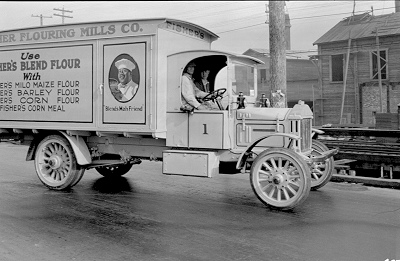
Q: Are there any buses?
A: No, there are no buses.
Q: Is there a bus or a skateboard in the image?
A: No, there are no buses or skateboards.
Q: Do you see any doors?
A: Yes, there is a door.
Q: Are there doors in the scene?
A: Yes, there is a door.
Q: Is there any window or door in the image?
A: Yes, there is a door.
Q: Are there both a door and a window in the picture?
A: Yes, there are both a door and a window.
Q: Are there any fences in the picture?
A: No, there are no fences.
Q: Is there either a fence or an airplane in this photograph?
A: No, there are no fences or airplanes.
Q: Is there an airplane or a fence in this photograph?
A: No, there are no fences or airplanes.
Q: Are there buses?
A: No, there are no buses.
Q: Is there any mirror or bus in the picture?
A: No, there are no buses or mirrors.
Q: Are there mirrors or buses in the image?
A: No, there are no buses or mirrors.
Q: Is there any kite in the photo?
A: No, there are no kites.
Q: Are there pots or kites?
A: No, there are no kites or pots.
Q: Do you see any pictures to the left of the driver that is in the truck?
A: Yes, there is a picture to the left of the driver.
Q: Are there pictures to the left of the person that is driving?
A: Yes, there is a picture to the left of the driver.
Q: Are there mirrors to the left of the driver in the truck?
A: No, there is a picture to the left of the driver.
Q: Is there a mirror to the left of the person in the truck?
A: No, there is a picture to the left of the driver.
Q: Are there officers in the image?
A: No, there are no officers.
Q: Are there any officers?
A: No, there are no officers.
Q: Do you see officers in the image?
A: No, there are no officers.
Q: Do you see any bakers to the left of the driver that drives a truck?
A: Yes, there is a baker to the left of the driver.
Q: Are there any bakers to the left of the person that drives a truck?
A: Yes, there is a baker to the left of the driver.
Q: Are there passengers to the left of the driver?
A: No, there is a baker to the left of the driver.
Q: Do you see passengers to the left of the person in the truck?
A: No, there is a baker to the left of the driver.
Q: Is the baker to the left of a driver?
A: Yes, the baker is to the left of a driver.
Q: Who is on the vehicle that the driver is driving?
A: The baker is on the truck.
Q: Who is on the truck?
A: The baker is on the truck.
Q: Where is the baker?
A: The baker is on the truck.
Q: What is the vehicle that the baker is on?
A: The vehicle is a truck.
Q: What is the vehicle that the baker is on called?
A: The vehicle is a truck.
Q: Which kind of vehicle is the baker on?
A: The baker is on the truck.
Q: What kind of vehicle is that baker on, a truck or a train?
A: The baker is on a truck.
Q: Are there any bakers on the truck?
A: Yes, there is a baker on the truck.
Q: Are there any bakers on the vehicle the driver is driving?
A: Yes, there is a baker on the truck.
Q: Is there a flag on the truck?
A: No, there is a baker on the truck.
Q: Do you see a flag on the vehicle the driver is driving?
A: No, there is a baker on the truck.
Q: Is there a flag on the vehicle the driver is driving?
A: No, there is a baker on the truck.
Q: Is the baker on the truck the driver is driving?
A: Yes, the baker is on the truck.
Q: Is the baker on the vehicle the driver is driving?
A: Yes, the baker is on the truck.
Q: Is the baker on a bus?
A: No, the baker is on the truck.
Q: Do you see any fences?
A: No, there are no fences.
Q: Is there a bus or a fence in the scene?
A: No, there are no fences or buses.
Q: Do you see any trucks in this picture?
A: Yes, there is a truck.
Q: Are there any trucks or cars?
A: Yes, there is a truck.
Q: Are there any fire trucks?
A: No, there are no fire trucks.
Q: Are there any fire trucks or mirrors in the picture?
A: No, there are no fire trucks or mirrors.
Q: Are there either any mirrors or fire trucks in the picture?
A: No, there are no fire trucks or mirrors.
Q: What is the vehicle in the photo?
A: The vehicle is a truck.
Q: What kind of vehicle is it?
A: The vehicle is a truck.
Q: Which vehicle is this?
A: This is a truck.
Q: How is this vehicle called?
A: This is a truck.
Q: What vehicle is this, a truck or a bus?
A: This is a truck.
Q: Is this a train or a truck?
A: This is a truck.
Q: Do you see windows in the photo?
A: Yes, there is a window.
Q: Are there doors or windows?
A: Yes, there is a window.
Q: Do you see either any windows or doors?
A: Yes, there is a window.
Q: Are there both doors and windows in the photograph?
A: Yes, there are both a window and doors.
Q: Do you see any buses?
A: No, there are no buses.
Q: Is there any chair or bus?
A: No, there are no buses or chairs.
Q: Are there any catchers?
A: No, there are no catchers.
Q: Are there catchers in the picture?
A: No, there are no catchers.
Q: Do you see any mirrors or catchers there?
A: No, there are no catchers or mirrors.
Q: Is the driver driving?
A: Yes, the driver is driving.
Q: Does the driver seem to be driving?
A: Yes, the driver is driving.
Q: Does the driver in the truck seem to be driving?
A: Yes, the driver is driving.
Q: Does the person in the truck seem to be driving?
A: Yes, the driver is driving.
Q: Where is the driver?
A: The driver is in the truck.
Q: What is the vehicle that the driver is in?
A: The vehicle is a truck.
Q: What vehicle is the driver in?
A: The driver is in the truck.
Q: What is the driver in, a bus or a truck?
A: The driver is in a truck.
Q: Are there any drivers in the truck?
A: Yes, there is a driver in the truck.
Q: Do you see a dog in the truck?
A: No, there is a driver in the truck.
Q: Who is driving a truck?
A: The driver is driving a truck.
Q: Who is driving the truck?
A: The driver is driving a truck.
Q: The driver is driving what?
A: The driver is driving a truck.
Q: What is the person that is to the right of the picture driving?
A: The driver is driving a truck.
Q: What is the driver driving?
A: The driver is driving a truck.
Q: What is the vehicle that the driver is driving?
A: The vehicle is a truck.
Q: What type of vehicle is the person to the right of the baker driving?
A: The driver is driving a truck.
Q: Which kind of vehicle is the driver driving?
A: The driver is driving a truck.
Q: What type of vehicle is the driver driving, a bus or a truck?
A: The driver is driving a truck.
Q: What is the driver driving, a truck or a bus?
A: The driver is driving a truck.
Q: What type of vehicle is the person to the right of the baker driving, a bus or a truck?
A: The driver is driving a truck.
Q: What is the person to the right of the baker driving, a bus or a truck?
A: The driver is driving a truck.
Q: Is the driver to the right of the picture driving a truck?
A: Yes, the driver is driving a truck.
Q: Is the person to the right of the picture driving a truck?
A: Yes, the driver is driving a truck.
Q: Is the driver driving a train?
A: No, the driver is driving a truck.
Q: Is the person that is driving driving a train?
A: No, the driver is driving a truck.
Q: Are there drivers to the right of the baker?
A: Yes, there is a driver to the right of the baker.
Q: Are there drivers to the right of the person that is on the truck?
A: Yes, there is a driver to the right of the baker.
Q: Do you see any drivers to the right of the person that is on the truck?
A: Yes, there is a driver to the right of the baker.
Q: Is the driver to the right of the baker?
A: Yes, the driver is to the right of the baker.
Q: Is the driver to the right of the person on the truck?
A: Yes, the driver is to the right of the baker.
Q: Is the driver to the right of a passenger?
A: No, the driver is to the right of the baker.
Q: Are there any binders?
A: No, there are no binders.